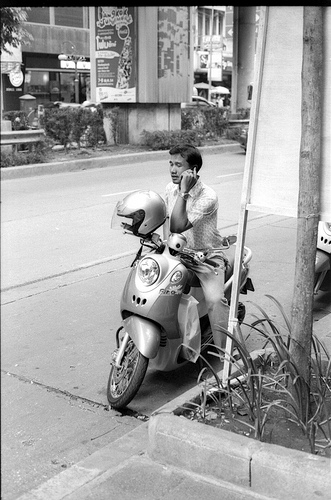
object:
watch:
[178, 192, 190, 202]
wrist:
[178, 189, 191, 198]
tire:
[106, 338, 149, 410]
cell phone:
[179, 171, 200, 187]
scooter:
[105, 186, 254, 411]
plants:
[243, 333, 330, 457]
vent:
[130, 294, 150, 308]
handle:
[200, 257, 219, 276]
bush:
[38, 101, 106, 154]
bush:
[140, 128, 205, 152]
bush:
[181, 99, 231, 141]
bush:
[0, 136, 51, 168]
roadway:
[0, 144, 330, 499]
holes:
[139, 295, 148, 307]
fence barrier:
[0, 127, 45, 156]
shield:
[109, 209, 144, 233]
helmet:
[110, 187, 167, 241]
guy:
[159, 135, 232, 363]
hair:
[168, 142, 203, 175]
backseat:
[223, 238, 242, 279]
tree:
[284, 4, 325, 421]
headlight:
[134, 252, 161, 286]